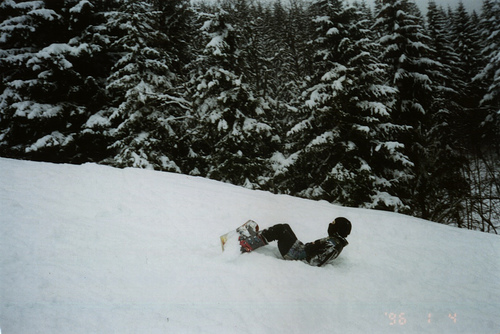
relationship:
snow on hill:
[0, 158, 498, 332] [1, 155, 476, 331]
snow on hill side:
[0, 158, 498, 332] [1, 154, 498, 332]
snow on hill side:
[0, 158, 498, 332] [298, 154, 497, 327]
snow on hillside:
[0, 158, 498, 332] [35, 158, 377, 306]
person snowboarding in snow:
[239, 214, 352, 266] [0, 158, 498, 332]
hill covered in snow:
[1, 155, 476, 331] [0, 158, 498, 332]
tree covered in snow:
[277, 0, 417, 211] [335, 116, 420, 211]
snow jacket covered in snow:
[278, 238, 350, 265] [324, 237, 336, 252]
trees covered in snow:
[0, 0, 495, 211] [31, 190, 207, 314]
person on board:
[239, 214, 352, 266] [213, 218, 260, 253]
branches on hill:
[471, 166, 497, 236] [1, 155, 476, 331]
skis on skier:
[217, 215, 267, 250] [213, 208, 355, 269]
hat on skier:
[329, 217, 351, 237] [220, 216, 352, 265]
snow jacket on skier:
[291, 238, 361, 260] [236, 217, 353, 269]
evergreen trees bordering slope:
[25, 3, 415, 141] [17, 146, 222, 318]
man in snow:
[220, 215, 350, 264] [0, 158, 498, 332]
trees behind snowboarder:
[0, 0, 90, 155] [219, 215, 352, 265]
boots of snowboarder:
[238, 222, 268, 254] [219, 215, 352, 265]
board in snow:
[207, 221, 252, 253] [31, 186, 208, 301]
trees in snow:
[0, 0, 90, 155] [0, 158, 498, 332]